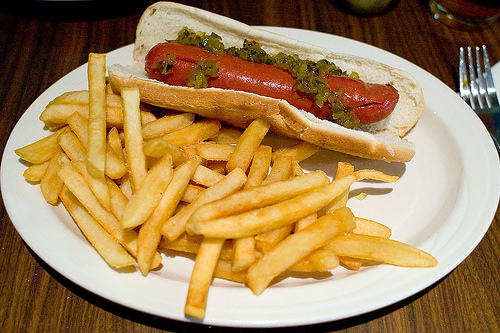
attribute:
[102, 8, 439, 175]
dog — hot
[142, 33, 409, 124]
hot dog — green, cooked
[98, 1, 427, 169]
bun — brown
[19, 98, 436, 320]
fries — golden, crispy, yellow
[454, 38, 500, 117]
fork — head, four-pronged, silver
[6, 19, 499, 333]
plate — white, round, full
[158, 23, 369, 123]
relish — green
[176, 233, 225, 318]
french fry — cooked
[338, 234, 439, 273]
french fry — cooked